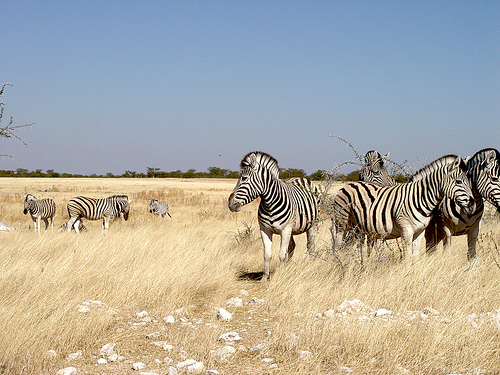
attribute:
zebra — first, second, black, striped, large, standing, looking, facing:
[226, 151, 318, 280]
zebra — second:
[330, 155, 475, 272]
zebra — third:
[362, 153, 394, 182]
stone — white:
[216, 303, 234, 323]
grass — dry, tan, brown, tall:
[2, 176, 498, 374]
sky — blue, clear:
[2, 0, 499, 178]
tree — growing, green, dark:
[147, 166, 160, 176]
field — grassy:
[1, 175, 498, 374]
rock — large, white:
[216, 307, 233, 320]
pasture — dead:
[4, 174, 499, 374]